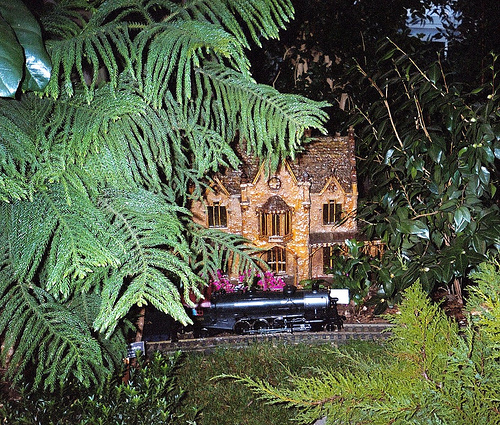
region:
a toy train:
[200, 281, 343, 338]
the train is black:
[170, 275, 345, 336]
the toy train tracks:
[350, 320, 405, 345]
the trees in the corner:
[265, 265, 490, 422]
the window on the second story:
[315, 195, 345, 221]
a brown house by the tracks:
[187, 130, 347, 285]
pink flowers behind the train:
[205, 260, 280, 290]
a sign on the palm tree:
[111, 335, 148, 360]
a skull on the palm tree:
[130, 342, 145, 354]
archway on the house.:
[255, 243, 300, 290]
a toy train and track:
[168, 278, 348, 338]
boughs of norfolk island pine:
[8, 6, 305, 383]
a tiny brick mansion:
[176, 117, 360, 282]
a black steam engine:
[188, 286, 345, 332]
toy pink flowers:
[185, 265, 302, 295]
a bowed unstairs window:
[246, 185, 296, 250]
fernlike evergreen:
[216, 302, 498, 424]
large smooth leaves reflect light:
[1, 3, 53, 110]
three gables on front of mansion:
[188, 160, 363, 229]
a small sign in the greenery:
[104, 329, 159, 397]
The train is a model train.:
[170, 267, 350, 349]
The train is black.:
[188, 275, 353, 349]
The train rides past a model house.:
[175, 119, 384, 361]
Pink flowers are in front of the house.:
[199, 259, 301, 301]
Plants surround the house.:
[0, 119, 499, 422]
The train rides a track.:
[120, 272, 422, 363]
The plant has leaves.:
[330, 96, 495, 318]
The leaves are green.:
[320, 119, 492, 318]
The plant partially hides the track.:
[0, 77, 270, 422]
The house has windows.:
[190, 132, 367, 296]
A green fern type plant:
[7, 8, 267, 376]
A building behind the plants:
[168, 131, 361, 293]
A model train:
[137, 280, 351, 342]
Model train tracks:
[75, 319, 407, 354]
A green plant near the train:
[342, 39, 494, 294]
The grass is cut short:
[155, 359, 392, 423]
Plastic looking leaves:
[0, 8, 73, 101]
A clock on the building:
[267, 176, 280, 193]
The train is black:
[154, 283, 355, 333]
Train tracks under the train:
[158, 321, 390, 350]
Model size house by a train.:
[165, 135, 437, 372]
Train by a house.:
[165, 234, 458, 346]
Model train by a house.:
[159, 242, 399, 334]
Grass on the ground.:
[196, 315, 388, 397]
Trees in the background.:
[299, 367, 431, 419]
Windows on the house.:
[238, 198, 333, 291]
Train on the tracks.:
[146, 247, 476, 393]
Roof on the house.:
[261, 111, 388, 201]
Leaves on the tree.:
[73, 145, 290, 352]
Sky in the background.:
[403, 15, 494, 58]